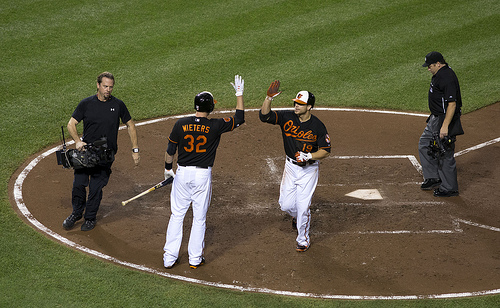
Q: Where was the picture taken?
A: Baseball field.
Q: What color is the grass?
A: Green.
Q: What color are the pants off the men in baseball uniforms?
A: White.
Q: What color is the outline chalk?
A: White.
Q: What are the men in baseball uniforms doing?
A: High fiving.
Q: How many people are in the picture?
A: 4.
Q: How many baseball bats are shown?
A: 1.